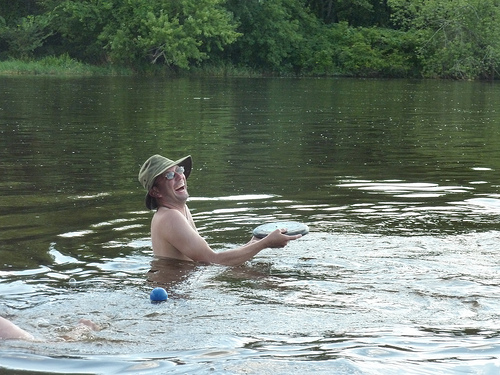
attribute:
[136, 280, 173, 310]
ball — blue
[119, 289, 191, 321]
ball — blue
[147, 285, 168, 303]
ball — floating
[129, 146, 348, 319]
person — smiling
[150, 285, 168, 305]
ball — blue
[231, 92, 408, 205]
water — untroubled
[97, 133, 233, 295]
man — swimming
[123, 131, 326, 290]
man — shirtless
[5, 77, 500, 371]
water — tranquil, rippling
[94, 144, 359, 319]
man — smiling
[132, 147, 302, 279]
person — smiling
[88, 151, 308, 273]
person — swimming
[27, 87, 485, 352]
water — blue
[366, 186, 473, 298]
ripples — clear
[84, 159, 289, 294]
person — swimming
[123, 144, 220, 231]
person — smiling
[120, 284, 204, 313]
ball water — blue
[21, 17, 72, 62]
trees — green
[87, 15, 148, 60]
trees — green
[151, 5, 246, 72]
trees — green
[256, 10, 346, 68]
trees — green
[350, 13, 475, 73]
trees — green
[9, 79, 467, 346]
water — calm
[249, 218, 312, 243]
frisbee — round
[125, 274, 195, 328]
ball — blue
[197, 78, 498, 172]
water — green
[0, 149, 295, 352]
fair-skinned man — smiling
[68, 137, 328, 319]
person — swimming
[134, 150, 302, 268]
person — swimming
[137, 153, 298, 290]
person — swimming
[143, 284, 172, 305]
ball — blue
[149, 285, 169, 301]
ball — blue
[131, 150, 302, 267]
man — swing, smiling